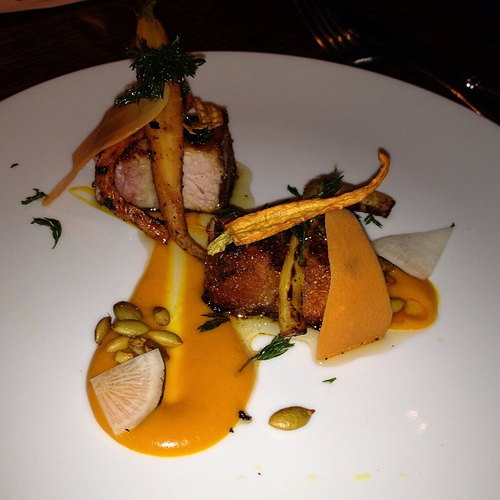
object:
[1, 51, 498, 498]
dish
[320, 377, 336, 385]
green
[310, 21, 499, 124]
fork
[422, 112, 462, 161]
ground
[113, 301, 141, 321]
pumpkin seed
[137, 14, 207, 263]
carrot slice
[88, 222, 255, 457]
mustard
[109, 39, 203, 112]
seaweed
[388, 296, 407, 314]
seed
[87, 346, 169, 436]
fruit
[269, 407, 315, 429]
pumpkin seed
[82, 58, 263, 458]
sauce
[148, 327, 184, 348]
seed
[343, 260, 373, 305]
yellow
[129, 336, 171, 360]
pumpkin seeds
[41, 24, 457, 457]
food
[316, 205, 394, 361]
pumpkin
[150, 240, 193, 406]
line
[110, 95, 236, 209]
meat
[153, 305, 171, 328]
pumpkin seed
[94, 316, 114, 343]
pumpkin seed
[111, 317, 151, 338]
pumpkin seed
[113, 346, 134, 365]
pumpkin seed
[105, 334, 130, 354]
seed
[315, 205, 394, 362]
mango